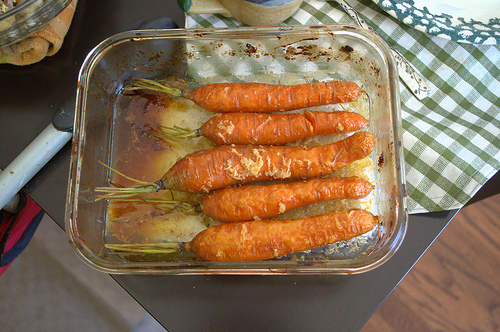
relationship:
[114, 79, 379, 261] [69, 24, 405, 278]
carrots in pan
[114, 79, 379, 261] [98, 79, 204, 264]
carrots have roots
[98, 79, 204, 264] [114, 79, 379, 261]
roots on carrots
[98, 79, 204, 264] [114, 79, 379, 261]
roots of carrots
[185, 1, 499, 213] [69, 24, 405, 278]
cloth near pan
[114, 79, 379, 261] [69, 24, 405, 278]
carrots are in a pan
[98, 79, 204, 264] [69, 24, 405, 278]
liquid in pan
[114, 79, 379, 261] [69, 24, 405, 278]
carrots are in pan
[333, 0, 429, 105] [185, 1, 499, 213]
handle on cloth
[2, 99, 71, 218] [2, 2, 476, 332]
handle on table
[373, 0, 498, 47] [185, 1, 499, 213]
plate on top of cloth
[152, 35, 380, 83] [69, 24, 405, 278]
bits are on side of pan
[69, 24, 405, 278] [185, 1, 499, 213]
pan on cloth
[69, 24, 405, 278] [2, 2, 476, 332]
pan on table